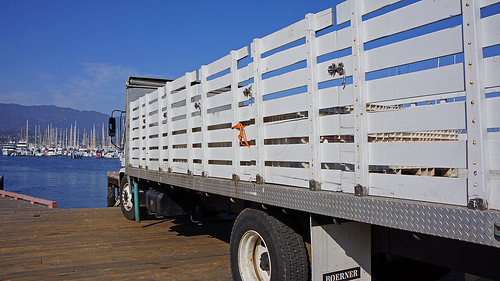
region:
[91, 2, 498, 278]
atruck in front an ocean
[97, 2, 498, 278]
truck is long and open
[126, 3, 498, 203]
white planks on side of truck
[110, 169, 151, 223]
front wheel of truck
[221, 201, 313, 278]
back wheel of truck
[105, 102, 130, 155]
a side driver mirror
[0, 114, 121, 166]
many yachts in an ocean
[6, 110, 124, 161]
masts of yachts are white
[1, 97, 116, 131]
a mountain in the background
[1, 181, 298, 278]
a dock of wood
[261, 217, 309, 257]
part of a wheel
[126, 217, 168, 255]
part of a floor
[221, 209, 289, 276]
part of a wheel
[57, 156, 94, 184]
part of a water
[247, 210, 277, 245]
edge of a wheel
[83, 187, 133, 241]
part of a floor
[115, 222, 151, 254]
part of a floor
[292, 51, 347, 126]
part of a lorry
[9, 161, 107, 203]
No waves in blue water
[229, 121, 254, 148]
Orange cord on outside of truck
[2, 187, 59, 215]
Red rail on a pier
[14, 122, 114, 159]
Boats docked in the water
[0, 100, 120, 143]
Mountain behind docked boats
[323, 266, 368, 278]
BOERNER written on a truck flap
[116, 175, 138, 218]
Front wheel of a parked truck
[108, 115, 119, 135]
Truck's side view mirror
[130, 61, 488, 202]
White fencing around a truck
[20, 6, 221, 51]
Blue sky above water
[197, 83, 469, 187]
this is a lorry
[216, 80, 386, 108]
the lorry is white in color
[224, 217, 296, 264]
this is a wheel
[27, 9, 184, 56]
this is the sky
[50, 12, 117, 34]
tyhe sky is blue in color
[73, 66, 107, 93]
these are the clouds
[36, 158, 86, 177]
this is a water body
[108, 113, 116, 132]
this is a side mirror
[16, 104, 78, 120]
this is a mountain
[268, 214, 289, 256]
the wheel is black in color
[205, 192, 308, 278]
a left back tire.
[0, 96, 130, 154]
a mountain range near boats.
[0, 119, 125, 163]
a dock filled with lots of boats.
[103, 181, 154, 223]
a tire on a truck.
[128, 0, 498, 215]
a flat bed on a truck.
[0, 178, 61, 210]
a pier near a truck.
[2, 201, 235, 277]
a large wooden dock.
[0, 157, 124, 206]
a large blue body of water.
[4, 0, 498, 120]
a clear blue sky.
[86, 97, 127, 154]
a side view mirror.